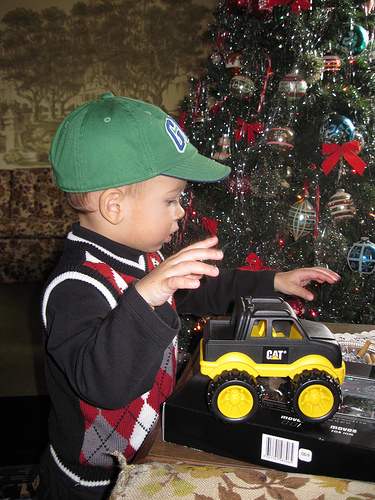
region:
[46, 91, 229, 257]
the boy is wearing a green cap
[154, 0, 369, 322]
a decorated Christmas tree is in the background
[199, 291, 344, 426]
a black and yellow toy truck is in front of the tree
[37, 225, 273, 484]
the boy is wearing a sweater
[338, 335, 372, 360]
an ashtray with cigarette butts is on the table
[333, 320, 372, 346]
a doily on the table is white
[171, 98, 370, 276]
red bows are on the Christmas tree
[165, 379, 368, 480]
a price code is on the black box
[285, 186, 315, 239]
a Christmas ornament is on the tree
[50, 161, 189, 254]
the child has his mouth open in surprise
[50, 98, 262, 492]
Little boy playing with a tractor.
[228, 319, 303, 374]
The tractor is a Cat.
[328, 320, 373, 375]
There is an ashtray with cigarettes next to the boy.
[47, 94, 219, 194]
The boy is wearing a green hat.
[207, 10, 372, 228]
A Christmas tree in the background.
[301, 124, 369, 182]
Red bows on a tree.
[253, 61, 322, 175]
Bulbs on a tree.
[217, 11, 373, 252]
Tinsel on the Christmas tree.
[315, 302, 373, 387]
The table is wooden.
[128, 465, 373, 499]
The sofa has a floral pattern.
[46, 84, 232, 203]
The little boy is wearing a green.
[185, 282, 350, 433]
The boy is playing with a toy truck.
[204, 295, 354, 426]
The toy truck is sitting on a box.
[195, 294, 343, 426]
The toy truck is black.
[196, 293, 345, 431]
The toy truck has big tires.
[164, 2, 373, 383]
The boy is standing beside a christmas tree.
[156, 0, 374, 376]
The christmas tree is decorated.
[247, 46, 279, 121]
There are candy canes on the tree.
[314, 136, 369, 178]
There are red bows on the christmas tree.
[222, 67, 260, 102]
Brightly colored ornaments hang on the tree.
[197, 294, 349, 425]
The yellow and black toy truck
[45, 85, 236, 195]
Green hat the boy is wearing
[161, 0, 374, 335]
Christmas tree behind the boy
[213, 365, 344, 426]
The wheels of the toy truck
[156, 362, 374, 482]
Black box the truck is sitting on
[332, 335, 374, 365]
Ash tray with cigarette butts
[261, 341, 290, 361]
Name on the side of the truck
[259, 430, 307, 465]
Bar code on the bottom of the box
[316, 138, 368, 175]
Red bow under the blue onrament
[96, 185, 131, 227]
The boy's ear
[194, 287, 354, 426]
yellow CAT truck with black roof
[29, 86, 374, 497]
little boy opening yellow truck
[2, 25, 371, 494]
this is an indoor Christmas scene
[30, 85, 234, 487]
little boy wearing green hat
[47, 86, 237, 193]
green hat with blue lettering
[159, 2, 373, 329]
Christmas tree with red ribbons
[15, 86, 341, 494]
boy wearing black shirt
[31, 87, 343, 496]
boy wearing red and grey and white argyle vest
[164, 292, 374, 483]
black box underneath yellow truck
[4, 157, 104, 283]
flowered sofa in background